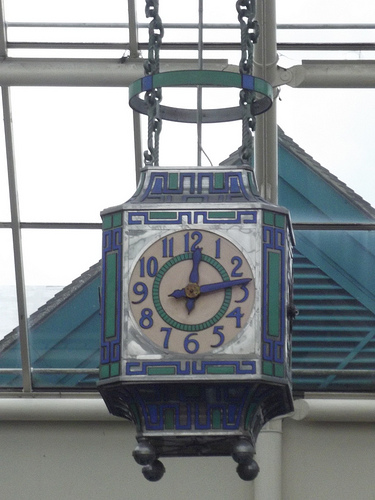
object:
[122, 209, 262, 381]
clock face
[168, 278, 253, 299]
clock arm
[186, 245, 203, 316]
clock arm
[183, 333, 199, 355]
number six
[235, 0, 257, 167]
chain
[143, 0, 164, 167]
chain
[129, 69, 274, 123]
ring support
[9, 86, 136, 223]
glass window piece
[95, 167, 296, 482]
aztec design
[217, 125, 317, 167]
top piece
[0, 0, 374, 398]
roof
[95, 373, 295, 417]
bottom piece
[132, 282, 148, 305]
number nine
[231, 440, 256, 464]
ball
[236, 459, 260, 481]
ball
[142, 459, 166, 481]
ball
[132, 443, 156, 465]
ball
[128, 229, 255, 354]
time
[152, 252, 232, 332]
circle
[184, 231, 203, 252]
arabic number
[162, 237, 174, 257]
arabic number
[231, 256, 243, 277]
arabic number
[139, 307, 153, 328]
arabic number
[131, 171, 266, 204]
decoration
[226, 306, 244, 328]
number 4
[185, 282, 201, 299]
flower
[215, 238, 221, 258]
blue number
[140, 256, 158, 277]
blue number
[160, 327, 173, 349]
blue number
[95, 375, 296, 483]
bottom part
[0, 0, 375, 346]
sky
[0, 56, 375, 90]
metal beam